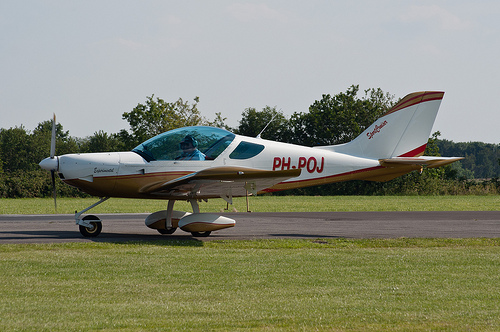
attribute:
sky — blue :
[6, 0, 498, 159]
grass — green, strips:
[5, 194, 497, 329]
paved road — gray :
[0, 212, 498, 236]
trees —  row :
[1, 85, 498, 197]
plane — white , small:
[39, 89, 466, 240]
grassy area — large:
[0, 237, 498, 330]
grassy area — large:
[0, 193, 499, 213]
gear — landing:
[140, 202, 240, 239]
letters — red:
[272, 150, 328, 177]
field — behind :
[15, 240, 485, 327]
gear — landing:
[74, 197, 238, 243]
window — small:
[231, 138, 272, 163]